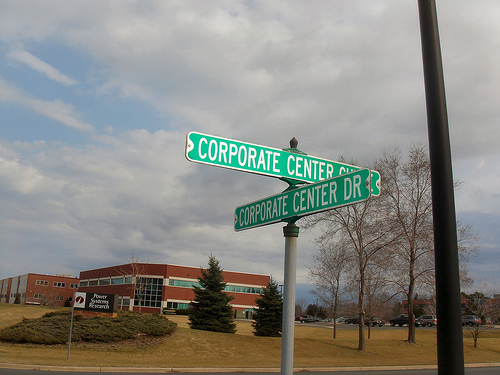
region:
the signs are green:
[147, 85, 415, 269]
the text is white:
[166, 107, 457, 277]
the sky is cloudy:
[136, 75, 381, 252]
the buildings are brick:
[14, 225, 326, 349]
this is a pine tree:
[177, 244, 251, 361]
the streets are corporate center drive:
[161, 90, 464, 330]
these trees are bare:
[301, 132, 446, 283]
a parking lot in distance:
[306, 295, 449, 322]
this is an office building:
[22, 240, 325, 357]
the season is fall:
[16, 0, 479, 367]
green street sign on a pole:
[17, 8, 449, 373]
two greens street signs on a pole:
[61, 120, 445, 340]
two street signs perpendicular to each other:
[144, 102, 396, 256]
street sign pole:
[260, 222, 317, 373]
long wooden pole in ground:
[380, 17, 475, 374]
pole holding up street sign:
[37, 261, 111, 373]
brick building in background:
[18, 260, 273, 318]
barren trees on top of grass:
[290, 140, 438, 374]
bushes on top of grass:
[42, 308, 182, 373]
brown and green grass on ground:
[154, 314, 246, 372]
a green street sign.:
[178, 128, 384, 182]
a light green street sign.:
[222, 165, 392, 227]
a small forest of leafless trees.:
[295, 148, 434, 354]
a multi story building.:
[70, 255, 273, 321]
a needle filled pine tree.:
[182, 257, 234, 340]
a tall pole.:
[413, 0, 470, 374]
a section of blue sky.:
[104, 103, 130, 125]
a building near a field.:
[0, 268, 88, 307]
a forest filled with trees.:
[293, 289, 498, 325]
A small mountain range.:
[272, 264, 486, 310]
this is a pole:
[423, 15, 456, 369]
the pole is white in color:
[283, 280, 292, 307]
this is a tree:
[200, 255, 228, 337]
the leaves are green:
[205, 278, 216, 302]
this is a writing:
[229, 193, 369, 202]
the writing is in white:
[195, 139, 253, 164]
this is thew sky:
[36, 63, 152, 175]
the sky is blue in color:
[4, 115, 28, 127]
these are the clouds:
[178, 52, 290, 112]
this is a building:
[96, 258, 153, 298]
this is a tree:
[207, 251, 231, 318]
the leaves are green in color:
[200, 310, 225, 321]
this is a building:
[110, 274, 200, 312]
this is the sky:
[38, 52, 139, 166]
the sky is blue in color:
[98, 100, 135, 117]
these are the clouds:
[188, 39, 370, 116]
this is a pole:
[418, 44, 450, 334]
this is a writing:
[196, 143, 271, 166]